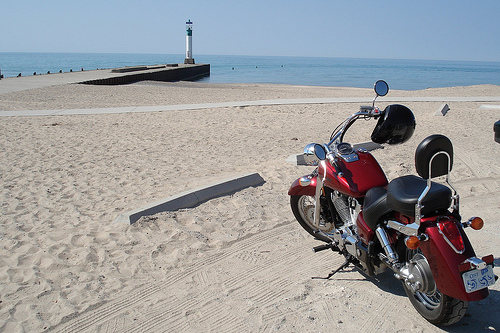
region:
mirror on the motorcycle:
[366, 78, 391, 96]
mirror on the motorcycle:
[305, 143, 330, 166]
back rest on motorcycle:
[416, 133, 453, 178]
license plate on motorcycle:
[456, 268, 498, 293]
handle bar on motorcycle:
[328, 155, 343, 175]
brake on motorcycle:
[369, 225, 397, 267]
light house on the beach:
[178, 15, 207, 65]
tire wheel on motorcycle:
[293, 187, 339, 239]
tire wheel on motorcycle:
[403, 243, 462, 327]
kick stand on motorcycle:
[326, 257, 357, 284]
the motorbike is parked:
[275, 85, 476, 317]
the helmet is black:
[361, 79, 432, 177]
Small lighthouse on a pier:
[183, 16, 193, 61]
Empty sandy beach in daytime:
[0, 79, 499, 331]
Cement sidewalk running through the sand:
[0, 94, 499, 116]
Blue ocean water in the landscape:
[0, 50, 497, 90]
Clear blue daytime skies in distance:
[0, 1, 497, 59]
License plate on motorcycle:
[460, 265, 498, 290]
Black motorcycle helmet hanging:
[371, 104, 415, 146]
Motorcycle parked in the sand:
[287, 78, 499, 326]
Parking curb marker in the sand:
[122, 162, 269, 226]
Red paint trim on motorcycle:
[315, 149, 389, 197]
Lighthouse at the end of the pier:
[183, 15, 195, 65]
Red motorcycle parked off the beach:
[287, 77, 498, 328]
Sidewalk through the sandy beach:
[3, 93, 498, 118]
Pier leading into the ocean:
[2, 62, 210, 91]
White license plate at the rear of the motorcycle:
[463, 263, 495, 293]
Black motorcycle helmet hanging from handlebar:
[371, 102, 414, 146]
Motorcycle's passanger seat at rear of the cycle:
[388, 133, 460, 219]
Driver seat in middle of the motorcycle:
[360, 173, 390, 221]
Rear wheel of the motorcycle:
[398, 238, 467, 326]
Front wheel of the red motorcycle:
[288, 182, 345, 243]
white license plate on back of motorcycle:
[464, 268, 497, 291]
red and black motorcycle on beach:
[286, 79, 498, 326]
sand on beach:
[41, 128, 118, 182]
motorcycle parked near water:
[286, 78, 497, 325]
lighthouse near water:
[182, 18, 195, 66]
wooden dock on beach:
[67, 60, 214, 84]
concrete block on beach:
[434, 95, 449, 118]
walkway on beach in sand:
[26, 90, 351, 128]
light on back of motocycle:
[467, 215, 484, 229]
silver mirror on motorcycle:
[371, 78, 388, 95]